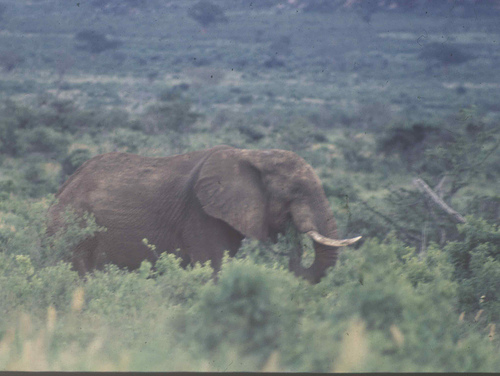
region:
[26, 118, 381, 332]
elephant in the brush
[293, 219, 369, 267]
elephant's ivory tusk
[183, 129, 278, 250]
ear of an elephant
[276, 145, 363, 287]
elephant's head with trunk and tusk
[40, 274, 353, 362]
area of green brush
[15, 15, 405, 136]
plain with green brush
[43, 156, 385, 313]
elephant putting food in its mouth with trunk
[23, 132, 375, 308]
gray elephant eating brush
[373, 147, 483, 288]
brush and dead logs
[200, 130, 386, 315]
elephant's head with trunk curled to mouth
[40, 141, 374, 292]
THIS IS AN ELEPHANT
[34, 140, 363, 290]
THE ELEPHANT IS BROWN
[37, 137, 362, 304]
THE ELEPHANT HAS WRINKLY SKIN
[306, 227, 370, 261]
THE ELEPHANT HAS A TUSK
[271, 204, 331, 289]
THE ELEPHANT IS EATING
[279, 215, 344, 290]
THE ELEPHANT IS USING IT'S TRUNK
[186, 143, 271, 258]
THE ELEPHANT HAS LARGE EARS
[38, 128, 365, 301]
THE ELEPHANT IS VERY BIG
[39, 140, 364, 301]
THE ELEPHANT IS SURROUNDED BY SHRUBS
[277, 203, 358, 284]
THIS IS AN ELEPHANT'S TRUNK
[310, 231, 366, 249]
ivory tusk of elephant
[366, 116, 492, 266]
fallen trees in a pile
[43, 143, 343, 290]
brown elephant in natural habitat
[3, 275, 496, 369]
brush is tall and green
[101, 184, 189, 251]
wrinkles on elephant's side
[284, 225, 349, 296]
elephant is eating grass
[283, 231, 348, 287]
frown elephants trunk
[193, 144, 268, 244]
elephants big brown ear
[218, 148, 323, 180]
mud on the elephant's head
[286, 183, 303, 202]
elephant's eye is small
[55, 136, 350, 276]
The elephant is grey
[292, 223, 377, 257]
The tusks are white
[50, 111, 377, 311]
Elephant with large tusks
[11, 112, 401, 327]
The elephant is eating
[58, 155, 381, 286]
The elephant is placing leaves in its mouth with its trunk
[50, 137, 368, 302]
The elephant is in dense foliage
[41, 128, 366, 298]
The elephant is grazing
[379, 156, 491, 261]
Log next to the elephant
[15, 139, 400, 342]
The elephant is in the bushes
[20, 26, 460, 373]
Green bushes and brown grass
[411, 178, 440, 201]
tree trunk sticking out in the forest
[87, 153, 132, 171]
elephant back hump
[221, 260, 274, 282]
top of shrubbery in front of elephant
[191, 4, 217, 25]
large tree in the distant background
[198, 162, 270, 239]
elephant ear from the side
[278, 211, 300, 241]
elephant shoving plant life in his mouth with trunk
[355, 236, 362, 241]
tip of elephat tusk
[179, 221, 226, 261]
upper part of elephant leg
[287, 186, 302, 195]
elephant eye from the side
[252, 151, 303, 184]
top of the elephant head